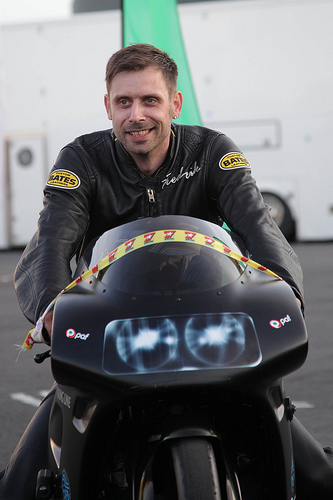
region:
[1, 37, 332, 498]
a man on a motorbike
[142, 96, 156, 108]
an eye of a man on a motorbike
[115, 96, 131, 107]
an eye of a man on a motorbike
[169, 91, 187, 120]
the ear of a man on a motorbike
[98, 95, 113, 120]
the ear of a man on a motorbike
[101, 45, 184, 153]
the smiling face of a man on a motorbike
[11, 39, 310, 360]
the rider is wearing a black coat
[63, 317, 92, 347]
the brand mark of the motor bike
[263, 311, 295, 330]
the ear of a man on a motorbike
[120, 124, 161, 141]
the mouth of a man on a motorbike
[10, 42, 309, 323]
a man on a motorcycle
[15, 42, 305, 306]
a man wearing a black jacket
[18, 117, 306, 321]
the jacket is leather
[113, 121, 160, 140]
the man is smiling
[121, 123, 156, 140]
the man's teeth are yellow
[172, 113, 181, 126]
the man is wearing an earring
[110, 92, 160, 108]
the man has blue eyes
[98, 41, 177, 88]
the man has brown hair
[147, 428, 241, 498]
the motorcycle tire is black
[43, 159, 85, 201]
the jacket has yellow patches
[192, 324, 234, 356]
part of a headlight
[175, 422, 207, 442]
edge of a guard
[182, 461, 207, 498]
part of a wheel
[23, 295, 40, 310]
part of a coat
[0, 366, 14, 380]
part of a road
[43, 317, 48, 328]
part of a finger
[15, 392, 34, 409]
part of a white line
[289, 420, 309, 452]
part of a trouser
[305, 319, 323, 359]
part of a road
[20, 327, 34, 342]
part of a rope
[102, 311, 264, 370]
strange headlights, possibly stickered on instead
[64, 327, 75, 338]
red+white+green round logo on either side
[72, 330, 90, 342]
the letters 'pa' & possibly 't' beside red-white-green round logos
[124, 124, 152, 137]
a goofy toothy smile on a somewhat goofy looking dude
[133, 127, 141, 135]
a couple middle teeth beginning to turn brown @ mouth's centre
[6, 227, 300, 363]
a bent yellow ribbon or tape w/ red+white+green designs & white frayed end edge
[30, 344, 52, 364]
a round-headed gear @ the side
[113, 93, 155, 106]
two deep-set, weary, bluegreen eyes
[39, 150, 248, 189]
BATES, twice, in yellow, in patches, on sleeve's shoulders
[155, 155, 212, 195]
Frederik [i think], in cursive, as a form of racer ID, beside thick zip w/ thick zip pull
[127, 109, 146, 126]
The nose of the man on the motorcycle.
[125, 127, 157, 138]
The mouth of the man on the motorcycle.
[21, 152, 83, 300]
The left arm of the man on the motorcycle.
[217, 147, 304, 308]
The right arm of the man on the motorcycle.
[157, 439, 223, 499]
The front wheel of the motorcycle.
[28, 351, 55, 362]
The left handle bar brake on the front of the motorcycle.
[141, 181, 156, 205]
The zipper on the man's jacket.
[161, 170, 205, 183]
The white writing on the man's jacket.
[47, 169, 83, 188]
The yellow and black patch on the left sleeve of the man's jacket.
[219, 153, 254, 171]
The yellow and black patch on the right sleeve of the man's jacket.